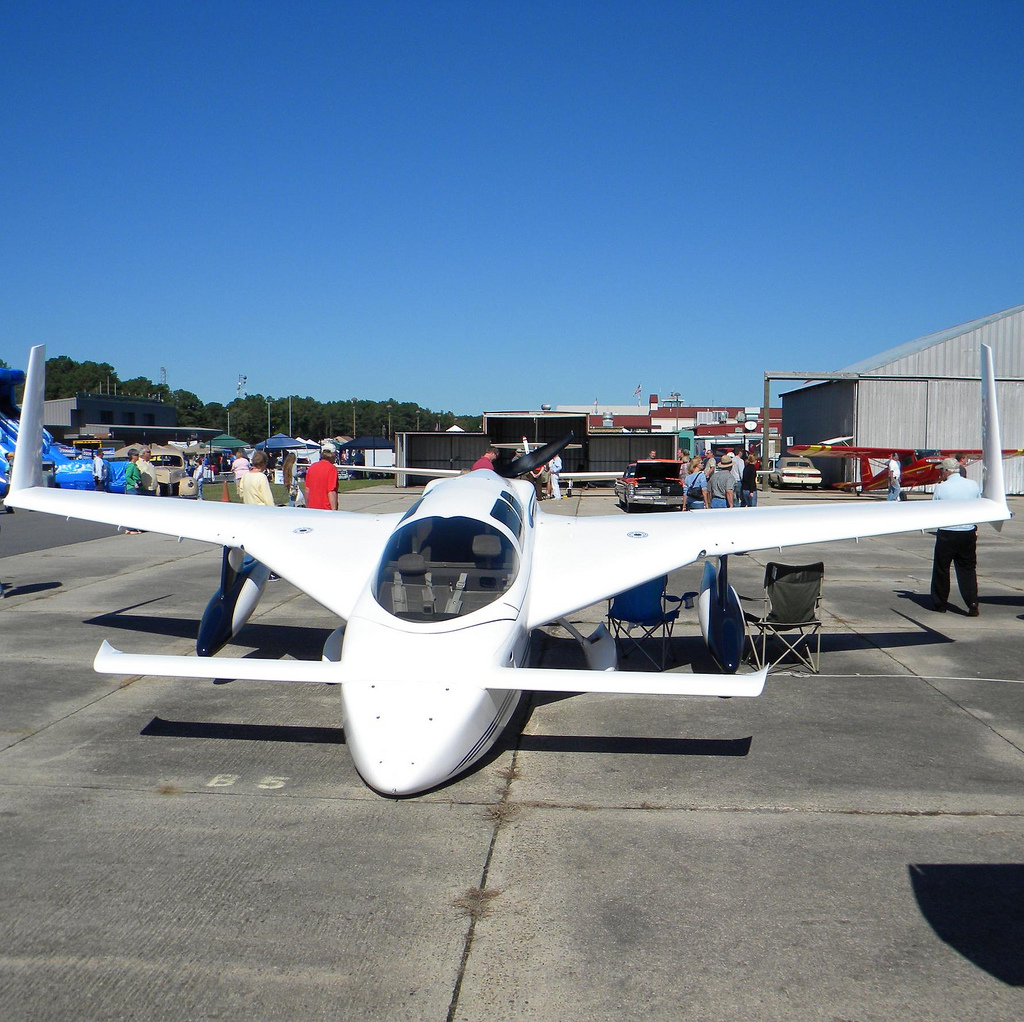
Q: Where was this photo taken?
A: At an airport.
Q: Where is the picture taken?
A: The airport.